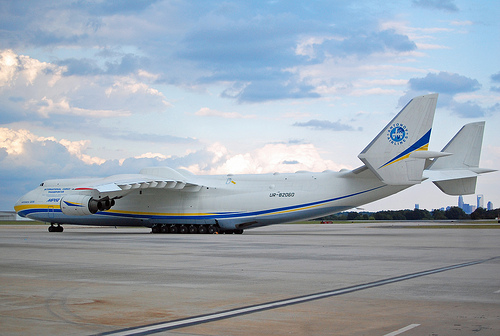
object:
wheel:
[48, 226, 55, 232]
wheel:
[57, 226, 63, 231]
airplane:
[13, 92, 497, 234]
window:
[40, 183, 44, 186]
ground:
[283, 113, 331, 165]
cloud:
[0, 0, 499, 173]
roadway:
[73, 224, 426, 323]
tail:
[357, 90, 498, 195]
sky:
[0, 2, 500, 211]